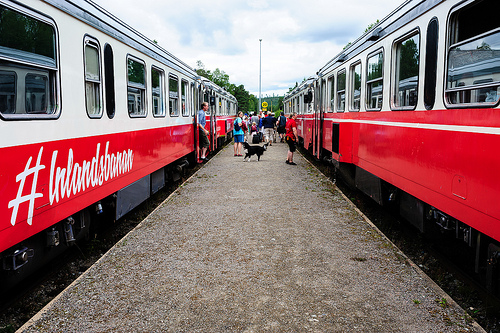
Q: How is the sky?
A: Cloudy.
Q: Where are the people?
A: In between the trains.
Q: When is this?
A: During the day.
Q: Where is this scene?
A: A train station.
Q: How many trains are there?
A: Two.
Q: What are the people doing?
A: Walking.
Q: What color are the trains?
A: Red and white.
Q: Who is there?
A: A crowd of people.